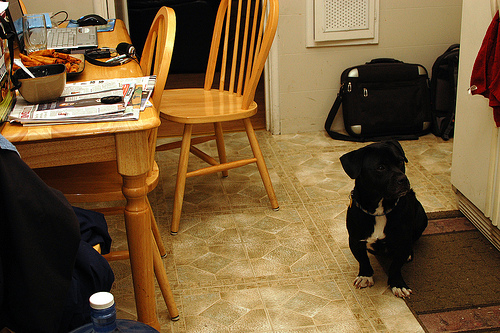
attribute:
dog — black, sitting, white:
[331, 139, 434, 299]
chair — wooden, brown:
[162, 0, 284, 235]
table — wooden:
[0, 15, 180, 331]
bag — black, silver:
[325, 58, 434, 142]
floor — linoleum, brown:
[159, 140, 459, 331]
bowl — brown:
[17, 67, 65, 103]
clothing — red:
[468, 11, 499, 132]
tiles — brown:
[158, 136, 341, 327]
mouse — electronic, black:
[78, 15, 106, 27]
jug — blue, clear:
[64, 289, 160, 331]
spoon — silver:
[14, 58, 36, 81]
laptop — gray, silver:
[4, 1, 97, 48]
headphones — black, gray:
[84, 40, 133, 68]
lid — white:
[89, 289, 114, 308]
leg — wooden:
[118, 136, 153, 329]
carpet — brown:
[383, 209, 499, 329]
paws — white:
[354, 273, 412, 296]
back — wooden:
[203, 0, 278, 110]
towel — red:
[465, 11, 499, 130]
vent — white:
[304, 0, 382, 47]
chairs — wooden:
[35, 0, 282, 323]